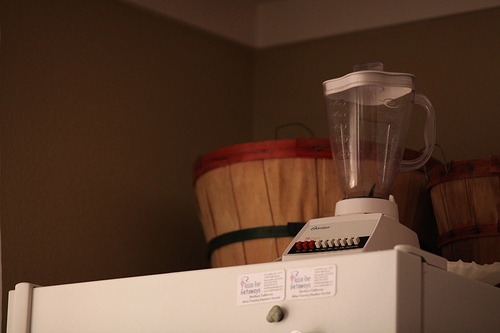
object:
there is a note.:
[235, 271, 287, 304]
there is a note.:
[289, 262, 336, 302]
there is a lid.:
[323, 63, 417, 108]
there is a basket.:
[190, 123, 439, 269]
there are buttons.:
[310, 237, 319, 249]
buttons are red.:
[306, 237, 314, 253]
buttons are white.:
[350, 232, 360, 249]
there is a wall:
[0, 1, 252, 317]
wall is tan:
[1, 0, 499, 332]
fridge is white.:
[3, 244, 498, 331]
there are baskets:
[421, 154, 499, 272]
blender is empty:
[271, 59, 435, 263]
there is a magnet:
[263, 304, 285, 324]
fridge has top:
[1, 245, 498, 301]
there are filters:
[446, 251, 499, 286]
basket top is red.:
[186, 127, 443, 184]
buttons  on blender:
[293, 240, 302, 255]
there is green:
[201, 221, 311, 264]